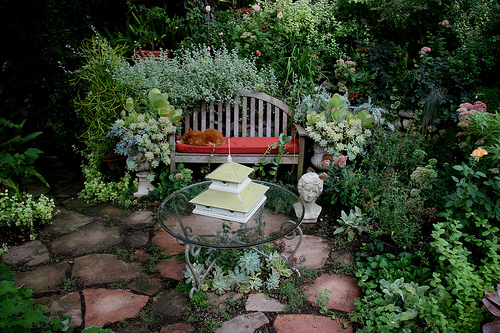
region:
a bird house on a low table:
[192, 137, 269, 224]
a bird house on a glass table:
[189, 135, 271, 221]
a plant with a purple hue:
[454, 102, 486, 129]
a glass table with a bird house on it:
[156, 177, 302, 247]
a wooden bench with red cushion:
[163, 85, 304, 178]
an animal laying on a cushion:
[180, 123, 223, 149]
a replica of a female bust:
[291, 171, 322, 221]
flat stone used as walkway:
[70, 252, 141, 283]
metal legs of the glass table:
[170, 193, 301, 298]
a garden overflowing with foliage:
[4, 4, 497, 331]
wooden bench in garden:
[145, 56, 329, 188]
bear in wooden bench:
[164, 80, 316, 172]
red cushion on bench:
[173, 126, 307, 153]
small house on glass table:
[192, 152, 275, 242]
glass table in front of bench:
[143, 152, 325, 282]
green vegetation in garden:
[437, 0, 493, 134]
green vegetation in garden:
[431, 126, 496, 316]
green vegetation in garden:
[301, 79, 378, 175]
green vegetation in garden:
[243, 5, 350, 73]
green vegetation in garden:
[94, 37, 189, 182]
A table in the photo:
[173, 174, 282, 251]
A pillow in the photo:
[182, 123, 306, 155]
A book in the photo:
[180, 182, 272, 219]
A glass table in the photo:
[200, 231, 269, 251]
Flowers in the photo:
[398, 223, 482, 323]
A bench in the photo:
[181, 95, 298, 161]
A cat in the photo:
[182, 122, 236, 152]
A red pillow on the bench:
[228, 127, 263, 156]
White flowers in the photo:
[308, 116, 375, 152]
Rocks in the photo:
[74, 239, 145, 302]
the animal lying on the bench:
[176, 127, 225, 144]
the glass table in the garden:
[155, 179, 301, 299]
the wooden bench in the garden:
[167, 89, 309, 184]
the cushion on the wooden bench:
[174, 134, 298, 153]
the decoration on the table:
[188, 137, 269, 223]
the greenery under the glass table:
[167, 204, 298, 289]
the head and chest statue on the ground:
[291, 169, 324, 224]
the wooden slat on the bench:
[241, 96, 246, 137]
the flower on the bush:
[252, 2, 260, 10]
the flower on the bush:
[470, 147, 487, 158]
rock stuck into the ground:
[76, 275, 153, 332]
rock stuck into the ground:
[216, 308, 267, 332]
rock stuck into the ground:
[240, 284, 294, 315]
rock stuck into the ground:
[270, 300, 356, 331]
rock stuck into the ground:
[297, 269, 372, 311]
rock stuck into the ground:
[278, 227, 335, 276]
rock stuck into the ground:
[117, 200, 163, 230]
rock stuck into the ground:
[45, 214, 122, 261]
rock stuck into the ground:
[0, 233, 54, 274]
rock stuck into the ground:
[58, 187, 100, 210]